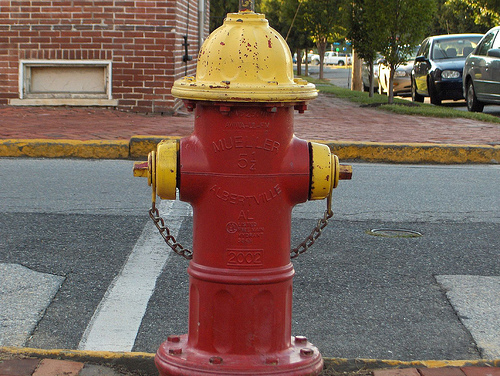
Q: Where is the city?
A: Albertville.